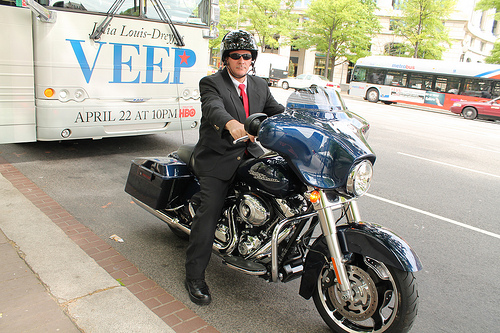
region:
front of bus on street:
[37, 0, 216, 140]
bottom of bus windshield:
[47, 1, 208, 21]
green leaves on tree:
[299, 2, 374, 62]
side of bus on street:
[350, 53, 498, 121]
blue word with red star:
[64, 38, 196, 85]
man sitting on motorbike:
[123, 29, 422, 331]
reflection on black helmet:
[223, 29, 255, 53]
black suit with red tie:
[182, 71, 279, 308]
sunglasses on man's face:
[226, 52, 255, 61]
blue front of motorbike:
[258, 87, 374, 195]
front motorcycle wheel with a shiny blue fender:
[296, 219, 424, 331]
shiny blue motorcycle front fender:
[296, 220, 424, 299]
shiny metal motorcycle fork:
[308, 186, 365, 306]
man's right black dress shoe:
[181, 273, 215, 306]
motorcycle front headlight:
[343, 156, 375, 200]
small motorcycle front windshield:
[282, 82, 352, 122]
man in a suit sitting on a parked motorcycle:
[121, 25, 424, 332]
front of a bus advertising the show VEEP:
[0, 1, 214, 145]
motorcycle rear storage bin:
[121, 153, 197, 216]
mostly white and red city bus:
[344, 51, 499, 126]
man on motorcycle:
[121, 29, 417, 331]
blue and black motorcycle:
[123, 87, 423, 331]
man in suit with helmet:
[186, 28, 293, 303]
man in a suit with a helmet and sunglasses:
[186, 30, 288, 306]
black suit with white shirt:
[184, 72, 286, 303]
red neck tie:
[239, 82, 249, 121]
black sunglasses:
[229, 51, 250, 60]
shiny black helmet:
[221, 30, 256, 63]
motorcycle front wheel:
[299, 220, 424, 331]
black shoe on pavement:
[181, 275, 211, 304]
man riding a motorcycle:
[115, 33, 437, 317]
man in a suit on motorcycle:
[103, 33, 425, 315]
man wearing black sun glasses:
[206, 20, 270, 83]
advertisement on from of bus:
[37, 10, 222, 142]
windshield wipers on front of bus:
[85, 0, 188, 40]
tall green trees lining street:
[212, 1, 498, 73]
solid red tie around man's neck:
[207, 87, 267, 122]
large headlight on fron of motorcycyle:
[341, 153, 390, 198]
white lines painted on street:
[417, 128, 481, 235]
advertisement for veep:
[58, 22, 205, 133]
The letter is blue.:
[64, 35, 105, 88]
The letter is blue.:
[106, 37, 143, 87]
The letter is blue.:
[141, 39, 172, 87]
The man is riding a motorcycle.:
[110, 13, 423, 331]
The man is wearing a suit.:
[168, 18, 290, 320]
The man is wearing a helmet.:
[183, 18, 284, 160]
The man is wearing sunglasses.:
[190, 20, 296, 167]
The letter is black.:
[68, 109, 85, 126]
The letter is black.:
[85, 106, 94, 123]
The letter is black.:
[92, 108, 103, 126]